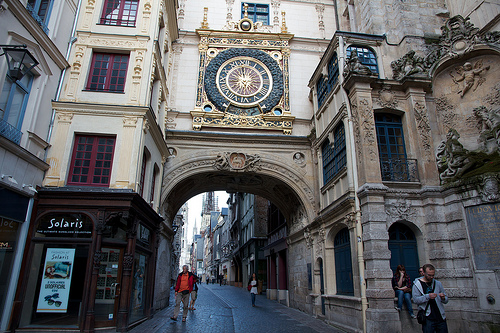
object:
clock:
[205, 47, 286, 115]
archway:
[154, 129, 321, 314]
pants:
[173, 292, 190, 317]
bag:
[417, 310, 427, 324]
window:
[96, 248, 121, 301]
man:
[411, 264, 447, 333]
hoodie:
[411, 276, 448, 319]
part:
[402, 245, 414, 249]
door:
[390, 223, 420, 288]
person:
[393, 264, 417, 319]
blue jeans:
[395, 289, 413, 315]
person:
[247, 273, 258, 306]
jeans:
[251, 293, 256, 304]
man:
[170, 265, 197, 322]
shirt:
[178, 272, 189, 293]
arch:
[160, 130, 318, 248]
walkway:
[134, 282, 348, 333]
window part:
[375, 112, 402, 125]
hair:
[422, 263, 435, 272]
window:
[374, 114, 410, 182]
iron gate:
[379, 157, 420, 182]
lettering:
[48, 218, 84, 229]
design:
[390, 14, 500, 184]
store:
[26, 186, 165, 333]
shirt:
[192, 284, 195, 291]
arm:
[193, 274, 197, 284]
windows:
[94, 161, 102, 168]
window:
[74, 159, 82, 166]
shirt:
[248, 278, 259, 286]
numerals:
[254, 95, 260, 101]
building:
[0, 0, 498, 329]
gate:
[375, 112, 410, 181]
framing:
[67, 134, 117, 187]